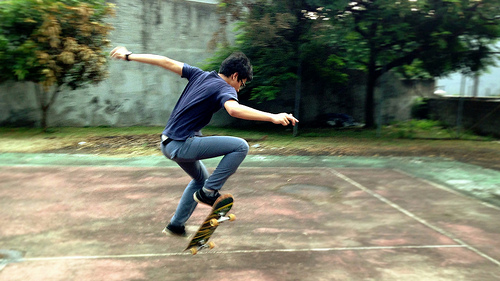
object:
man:
[110, 46, 300, 242]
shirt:
[161, 63, 239, 141]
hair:
[218, 51, 254, 82]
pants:
[158, 135, 249, 226]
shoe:
[161, 222, 193, 240]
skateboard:
[182, 193, 237, 255]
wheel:
[210, 218, 217, 226]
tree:
[0, 0, 117, 132]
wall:
[118, 1, 188, 44]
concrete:
[3, 161, 499, 279]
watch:
[125, 52, 133, 61]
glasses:
[240, 78, 246, 87]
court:
[2, 169, 492, 274]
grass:
[3, 128, 152, 140]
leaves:
[3, 4, 45, 24]